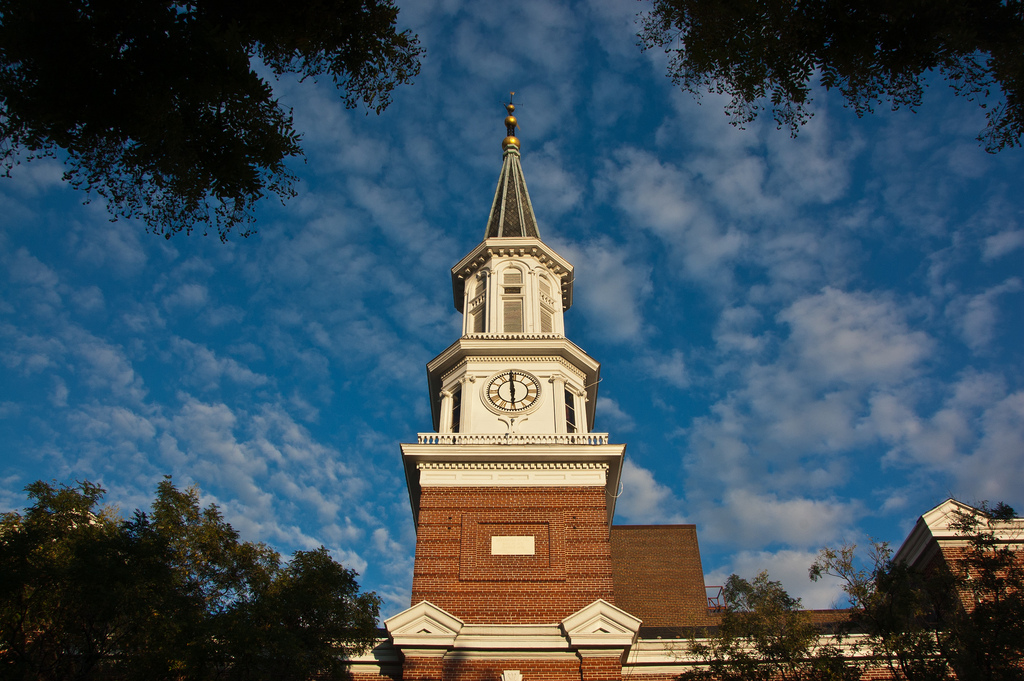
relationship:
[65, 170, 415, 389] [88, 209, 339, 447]
cloud in sky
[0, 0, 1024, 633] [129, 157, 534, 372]
sky in cloud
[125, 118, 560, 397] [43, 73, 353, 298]
cloud in sky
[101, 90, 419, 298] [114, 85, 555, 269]
sky in cloud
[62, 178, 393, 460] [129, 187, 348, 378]
cloud in sky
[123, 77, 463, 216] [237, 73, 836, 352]
cloud in sky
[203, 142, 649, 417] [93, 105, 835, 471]
cloud in sky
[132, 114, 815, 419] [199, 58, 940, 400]
cloud in sky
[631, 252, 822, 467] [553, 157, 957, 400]
cloud in sky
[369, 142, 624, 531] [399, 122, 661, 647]
clock on tower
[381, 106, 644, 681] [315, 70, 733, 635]
buidling on buidling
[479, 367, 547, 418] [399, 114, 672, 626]
clock on clock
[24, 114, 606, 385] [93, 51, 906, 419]
clouds in sky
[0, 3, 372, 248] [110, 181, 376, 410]
tree branch in sky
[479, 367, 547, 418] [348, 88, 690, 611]
clock on tower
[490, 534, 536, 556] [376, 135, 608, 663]
sign on wall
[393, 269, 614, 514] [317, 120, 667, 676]
window on tower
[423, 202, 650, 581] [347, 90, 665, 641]
crown on tower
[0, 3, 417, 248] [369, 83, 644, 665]
tree branch in front tower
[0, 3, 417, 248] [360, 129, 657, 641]
tree branch in tower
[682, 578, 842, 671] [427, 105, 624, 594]
tree front of tower